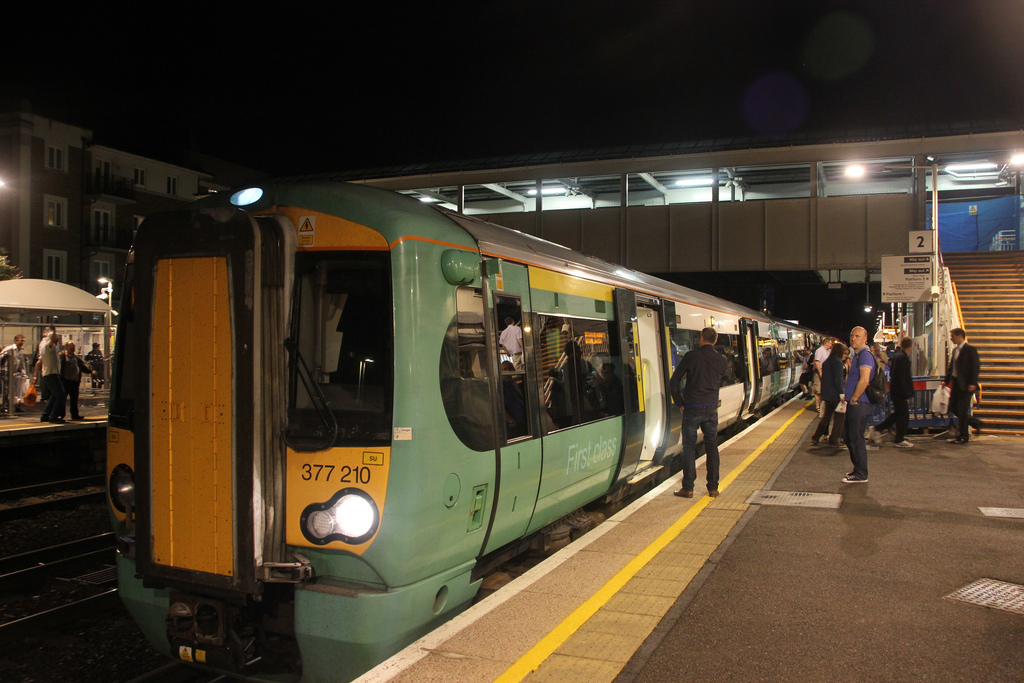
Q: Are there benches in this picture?
A: No, there are no benches.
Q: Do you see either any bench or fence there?
A: No, there are no benches or fences.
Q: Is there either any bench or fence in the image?
A: No, there are no benches or fences.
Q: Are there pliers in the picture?
A: No, there are no pliers.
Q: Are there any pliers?
A: No, there are no pliers.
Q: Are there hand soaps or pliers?
A: No, there are no pliers or hand soaps.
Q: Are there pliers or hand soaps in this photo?
A: No, there are no pliers or hand soaps.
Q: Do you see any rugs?
A: No, there are no rugs.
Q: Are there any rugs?
A: No, there are no rugs.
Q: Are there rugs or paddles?
A: No, there are no rugs or paddles.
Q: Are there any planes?
A: No, there are no planes.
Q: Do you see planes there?
A: No, there are no planes.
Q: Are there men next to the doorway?
A: Yes, there is a man next to the doorway.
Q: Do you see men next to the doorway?
A: Yes, there is a man next to the doorway.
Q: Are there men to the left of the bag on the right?
A: Yes, there is a man to the left of the backpack.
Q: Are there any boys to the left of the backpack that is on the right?
A: No, there is a man to the left of the backpack.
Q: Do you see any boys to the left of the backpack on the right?
A: No, there is a man to the left of the backpack.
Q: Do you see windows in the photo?
A: Yes, there is a window.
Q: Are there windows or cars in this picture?
A: Yes, there is a window.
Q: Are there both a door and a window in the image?
A: Yes, there are both a window and a door.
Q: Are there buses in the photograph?
A: No, there are no buses.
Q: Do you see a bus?
A: No, there are no buses.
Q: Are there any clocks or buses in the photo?
A: No, there are no buses or clocks.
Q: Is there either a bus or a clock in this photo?
A: No, there are no buses or clocks.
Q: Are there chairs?
A: No, there are no chairs.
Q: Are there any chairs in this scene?
A: No, there are no chairs.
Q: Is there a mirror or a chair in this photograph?
A: No, there are no chairs or mirrors.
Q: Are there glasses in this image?
A: No, there are no glasses.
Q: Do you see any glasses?
A: No, there are no glasses.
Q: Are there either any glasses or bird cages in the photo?
A: No, there are no glasses or bird cages.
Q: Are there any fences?
A: No, there are no fences.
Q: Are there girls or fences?
A: No, there are no fences or girls.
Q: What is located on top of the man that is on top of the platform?
A: The shirt is on top of the man.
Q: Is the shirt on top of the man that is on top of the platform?
A: Yes, the shirt is on top of the man.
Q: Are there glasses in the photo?
A: No, there are no glasses.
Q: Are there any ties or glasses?
A: No, there are no glasses or ties.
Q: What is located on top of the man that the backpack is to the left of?
A: The suit is on top of the man.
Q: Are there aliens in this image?
A: No, there are no aliens.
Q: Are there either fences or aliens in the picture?
A: No, there are no aliens or fences.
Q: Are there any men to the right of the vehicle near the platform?
A: Yes, there is a man to the right of the train.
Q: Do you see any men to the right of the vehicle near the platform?
A: Yes, there is a man to the right of the train.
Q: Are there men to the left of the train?
A: No, the man is to the right of the train.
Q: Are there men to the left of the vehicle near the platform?
A: No, the man is to the right of the train.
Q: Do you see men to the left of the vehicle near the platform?
A: No, the man is to the right of the train.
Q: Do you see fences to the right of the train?
A: No, there is a man to the right of the train.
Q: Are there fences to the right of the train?
A: No, there is a man to the right of the train.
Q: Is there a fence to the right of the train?
A: No, there is a man to the right of the train.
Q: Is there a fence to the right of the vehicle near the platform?
A: No, there is a man to the right of the train.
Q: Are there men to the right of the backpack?
A: Yes, there is a man to the right of the backpack.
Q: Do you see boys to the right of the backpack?
A: No, there is a man to the right of the backpack.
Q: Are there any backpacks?
A: Yes, there is a backpack.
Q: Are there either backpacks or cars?
A: Yes, there is a backpack.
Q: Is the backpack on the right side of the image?
A: Yes, the backpack is on the right of the image.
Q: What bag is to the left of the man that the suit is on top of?
A: The bag is a backpack.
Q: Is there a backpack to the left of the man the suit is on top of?
A: Yes, there is a backpack to the left of the man.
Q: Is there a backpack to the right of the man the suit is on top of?
A: No, the backpack is to the left of the man.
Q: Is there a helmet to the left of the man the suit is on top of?
A: No, there is a backpack to the left of the man.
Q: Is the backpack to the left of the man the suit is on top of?
A: Yes, the backpack is to the left of the man.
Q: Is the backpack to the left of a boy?
A: No, the backpack is to the left of the man.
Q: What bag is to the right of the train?
A: The bag is a backpack.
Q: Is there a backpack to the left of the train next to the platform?
A: No, the backpack is to the right of the train.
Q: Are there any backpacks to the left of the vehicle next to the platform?
A: No, the backpack is to the right of the train.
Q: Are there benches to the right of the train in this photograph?
A: No, there is a backpack to the right of the train.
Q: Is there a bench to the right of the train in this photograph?
A: No, there is a backpack to the right of the train.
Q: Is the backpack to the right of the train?
A: Yes, the backpack is to the right of the train.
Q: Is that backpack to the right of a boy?
A: No, the backpack is to the right of the train.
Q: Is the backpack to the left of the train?
A: No, the backpack is to the right of the train.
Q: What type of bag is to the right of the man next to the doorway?
A: The bag is a backpack.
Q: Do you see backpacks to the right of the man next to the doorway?
A: Yes, there is a backpack to the right of the man.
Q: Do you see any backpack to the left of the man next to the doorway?
A: No, the backpack is to the right of the man.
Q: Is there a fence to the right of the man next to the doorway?
A: No, there is a backpack to the right of the man.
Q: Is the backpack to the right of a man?
A: Yes, the backpack is to the right of a man.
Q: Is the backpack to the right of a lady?
A: No, the backpack is to the right of a man.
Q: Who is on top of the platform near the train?
A: The man is on top of the platform.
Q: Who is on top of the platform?
A: The man is on top of the platform.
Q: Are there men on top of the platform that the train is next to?
A: Yes, there is a man on top of the platform.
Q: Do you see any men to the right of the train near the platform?
A: Yes, there is a man to the right of the train.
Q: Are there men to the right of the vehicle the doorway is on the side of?
A: Yes, there is a man to the right of the train.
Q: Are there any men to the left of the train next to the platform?
A: No, the man is to the right of the train.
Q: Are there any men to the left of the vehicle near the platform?
A: No, the man is to the right of the train.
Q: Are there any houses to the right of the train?
A: No, there is a man to the right of the train.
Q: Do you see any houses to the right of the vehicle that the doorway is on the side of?
A: No, there is a man to the right of the train.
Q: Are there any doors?
A: Yes, there is a door.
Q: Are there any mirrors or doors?
A: Yes, there is a door.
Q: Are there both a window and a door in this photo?
A: Yes, there are both a door and a window.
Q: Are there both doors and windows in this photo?
A: Yes, there are both a door and windows.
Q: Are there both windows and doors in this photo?
A: Yes, there are both a door and windows.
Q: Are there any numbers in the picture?
A: Yes, there are numbers.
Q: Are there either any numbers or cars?
A: Yes, there are numbers.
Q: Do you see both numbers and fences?
A: No, there are numbers but no fences.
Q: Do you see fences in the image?
A: No, there are no fences.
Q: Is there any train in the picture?
A: Yes, there is a train.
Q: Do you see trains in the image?
A: Yes, there is a train.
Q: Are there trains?
A: Yes, there is a train.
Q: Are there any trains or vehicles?
A: Yes, there is a train.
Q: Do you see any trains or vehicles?
A: Yes, there is a train.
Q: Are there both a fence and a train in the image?
A: No, there is a train but no fences.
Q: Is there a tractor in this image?
A: No, there are no tractors.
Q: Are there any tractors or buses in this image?
A: No, there are no tractors or buses.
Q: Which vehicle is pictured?
A: The vehicle is a train.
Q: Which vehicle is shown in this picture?
A: The vehicle is a train.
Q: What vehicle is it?
A: The vehicle is a train.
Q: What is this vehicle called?
A: This is a train.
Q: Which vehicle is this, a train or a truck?
A: This is a train.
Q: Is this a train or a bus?
A: This is a train.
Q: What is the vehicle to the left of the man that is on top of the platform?
A: The vehicle is a train.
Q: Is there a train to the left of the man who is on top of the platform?
A: Yes, there is a train to the left of the man.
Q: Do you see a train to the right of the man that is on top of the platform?
A: No, the train is to the left of the man.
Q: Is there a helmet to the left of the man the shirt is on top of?
A: No, there is a train to the left of the man.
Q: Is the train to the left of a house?
A: No, the train is to the left of the man.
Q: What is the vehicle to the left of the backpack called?
A: The vehicle is a train.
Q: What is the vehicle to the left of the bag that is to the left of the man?
A: The vehicle is a train.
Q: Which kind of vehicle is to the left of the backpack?
A: The vehicle is a train.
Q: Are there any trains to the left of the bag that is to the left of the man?
A: Yes, there is a train to the left of the backpack.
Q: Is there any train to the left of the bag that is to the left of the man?
A: Yes, there is a train to the left of the backpack.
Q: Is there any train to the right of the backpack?
A: No, the train is to the left of the backpack.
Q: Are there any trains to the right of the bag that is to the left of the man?
A: No, the train is to the left of the backpack.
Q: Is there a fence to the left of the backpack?
A: No, there is a train to the left of the backpack.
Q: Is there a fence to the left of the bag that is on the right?
A: No, there is a train to the left of the backpack.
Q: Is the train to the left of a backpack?
A: Yes, the train is to the left of a backpack.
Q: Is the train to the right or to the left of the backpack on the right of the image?
A: The train is to the left of the backpack.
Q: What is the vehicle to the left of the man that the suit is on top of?
A: The vehicle is a train.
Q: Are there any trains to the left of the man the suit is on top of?
A: Yes, there is a train to the left of the man.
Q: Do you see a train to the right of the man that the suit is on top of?
A: No, the train is to the left of the man.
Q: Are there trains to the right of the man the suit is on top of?
A: No, the train is to the left of the man.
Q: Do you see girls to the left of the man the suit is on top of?
A: No, there is a train to the left of the man.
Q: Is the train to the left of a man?
A: Yes, the train is to the left of a man.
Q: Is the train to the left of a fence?
A: No, the train is to the left of a man.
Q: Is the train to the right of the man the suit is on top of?
A: No, the train is to the left of the man.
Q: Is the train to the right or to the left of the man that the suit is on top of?
A: The train is to the left of the man.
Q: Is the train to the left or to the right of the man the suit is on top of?
A: The train is to the left of the man.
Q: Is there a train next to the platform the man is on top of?
A: Yes, there is a train next to the platform.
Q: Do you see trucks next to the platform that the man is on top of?
A: No, there is a train next to the platform.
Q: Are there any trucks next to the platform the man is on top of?
A: No, there is a train next to the platform.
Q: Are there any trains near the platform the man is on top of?
A: Yes, there is a train near the platform.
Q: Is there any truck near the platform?
A: No, there is a train near the platform.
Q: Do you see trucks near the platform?
A: No, there is a train near the platform.